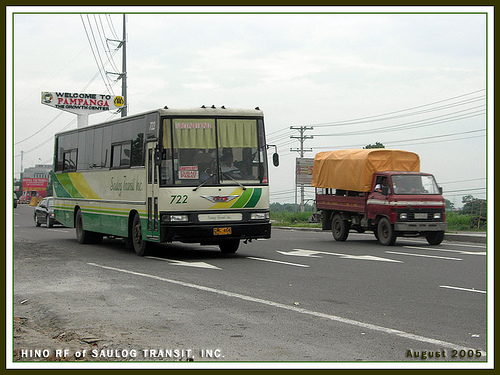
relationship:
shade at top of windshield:
[164, 117, 261, 151] [162, 117, 266, 186]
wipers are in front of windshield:
[194, 166, 245, 189] [162, 117, 266, 186]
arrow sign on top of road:
[148, 253, 221, 276] [14, 232, 483, 374]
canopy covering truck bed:
[308, 148, 423, 194] [312, 187, 374, 216]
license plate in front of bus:
[209, 223, 235, 237] [48, 111, 272, 259]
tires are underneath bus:
[129, 216, 149, 256] [48, 111, 272, 259]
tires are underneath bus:
[73, 208, 103, 249] [48, 111, 272, 259]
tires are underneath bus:
[217, 234, 242, 254] [48, 111, 272, 259]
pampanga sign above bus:
[41, 92, 125, 119] [48, 111, 272, 259]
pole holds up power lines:
[289, 119, 315, 224] [312, 106, 500, 142]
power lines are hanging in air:
[312, 106, 500, 142] [143, 10, 498, 99]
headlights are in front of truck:
[399, 212, 408, 222] [306, 147, 451, 246]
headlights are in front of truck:
[433, 214, 440, 222] [306, 147, 451, 246]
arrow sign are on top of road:
[403, 245, 485, 256] [14, 232, 483, 374]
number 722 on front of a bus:
[168, 191, 190, 208] [48, 111, 272, 259]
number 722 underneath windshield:
[168, 191, 190, 208] [162, 117, 266, 186]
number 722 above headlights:
[168, 191, 190, 208] [169, 213, 191, 223]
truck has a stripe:
[306, 147, 451, 246] [371, 198, 446, 207]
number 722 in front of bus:
[168, 191, 190, 208] [48, 111, 272, 259]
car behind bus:
[27, 198, 60, 228] [48, 111, 272, 259]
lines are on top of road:
[117, 279, 326, 306] [14, 232, 483, 374]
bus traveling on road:
[48, 111, 272, 259] [14, 232, 483, 374]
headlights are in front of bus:
[169, 213, 191, 223] [48, 111, 272, 259]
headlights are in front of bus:
[250, 213, 268, 221] [48, 111, 272, 259]